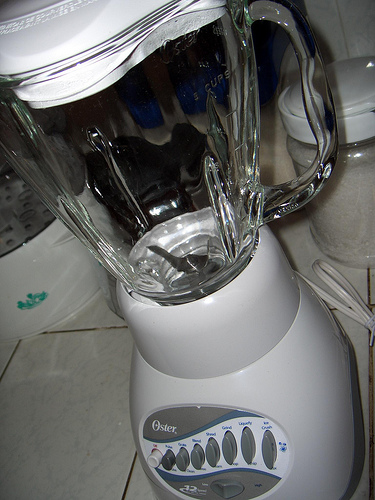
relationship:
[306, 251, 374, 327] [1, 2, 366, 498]
cord on blender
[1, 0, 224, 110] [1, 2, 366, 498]
cover on blender